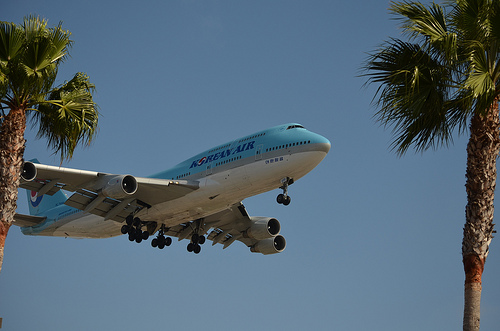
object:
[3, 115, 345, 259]
airplane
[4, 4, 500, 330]
sky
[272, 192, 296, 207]
wheels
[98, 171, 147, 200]
engine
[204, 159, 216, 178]
windows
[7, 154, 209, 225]
wing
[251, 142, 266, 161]
door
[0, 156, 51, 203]
tail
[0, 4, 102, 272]
tree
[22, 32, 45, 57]
leaves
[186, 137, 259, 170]
logo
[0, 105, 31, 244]
trunk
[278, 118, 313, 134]
cockpit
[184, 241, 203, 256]
wheel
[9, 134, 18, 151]
bark